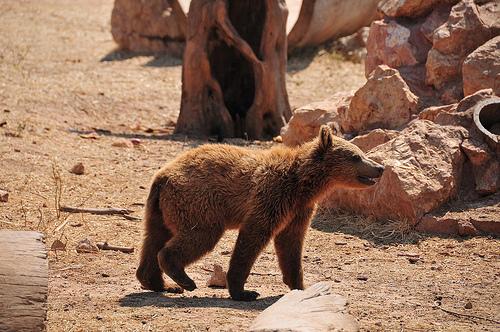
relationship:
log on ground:
[2, 228, 52, 330] [2, 4, 492, 328]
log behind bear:
[0, 228, 52, 331] [125, 117, 399, 294]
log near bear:
[2, 228, 52, 330] [139, 124, 392, 304]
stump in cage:
[168, 0, 294, 146] [2, 0, 497, 331]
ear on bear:
[324, 117, 340, 138] [139, 124, 392, 304]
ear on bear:
[317, 124, 333, 148] [139, 124, 392, 304]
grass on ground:
[303, 220, 496, 329] [2, 4, 492, 328]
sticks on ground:
[303, 208, 497, 327] [2, 4, 492, 328]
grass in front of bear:
[303, 220, 496, 329] [139, 124, 392, 304]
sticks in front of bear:
[303, 208, 497, 327] [139, 124, 392, 304]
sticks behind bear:
[0, 2, 180, 329] [119, 113, 389, 305]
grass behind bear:
[0, 0, 187, 328] [119, 113, 389, 305]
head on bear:
[314, 120, 387, 188] [119, 113, 389, 305]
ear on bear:
[317, 120, 333, 150] [132, 117, 382, 302]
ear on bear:
[324, 120, 340, 138] [132, 117, 382, 302]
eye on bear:
[347, 155, 361, 162] [139, 124, 392, 304]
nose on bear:
[371, 160, 388, 174] [125, 117, 399, 294]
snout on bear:
[371, 160, 388, 177] [139, 124, 392, 304]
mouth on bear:
[353, 169, 383, 188] [139, 124, 392, 304]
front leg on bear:
[226, 210, 284, 307] [139, 124, 392, 304]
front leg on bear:
[271, 220, 306, 289] [139, 124, 392, 304]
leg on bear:
[157, 209, 224, 279] [139, 124, 392, 304]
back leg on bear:
[137, 202, 184, 296] [139, 124, 392, 304]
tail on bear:
[140, 163, 181, 213] [139, 124, 392, 304]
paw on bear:
[219, 286, 264, 303] [139, 124, 392, 304]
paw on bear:
[171, 272, 200, 291] [139, 124, 392, 304]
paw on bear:
[138, 254, 168, 289] [139, 124, 392, 304]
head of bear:
[318, 120, 386, 190] [141, 164, 349, 332]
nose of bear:
[376, 165, 385, 174] [128, 123, 394, 321]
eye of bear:
[347, 155, 361, 162] [132, 135, 388, 272]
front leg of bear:
[273, 211, 313, 289] [120, 125, 369, 332]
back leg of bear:
[137, 197, 174, 287] [138, 165, 331, 328]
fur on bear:
[191, 152, 257, 196] [139, 124, 392, 304]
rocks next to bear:
[382, 99, 455, 204] [142, 142, 378, 321]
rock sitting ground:
[294, 57, 398, 127] [371, 250, 468, 290]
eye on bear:
[345, 152, 360, 164] [135, 121, 387, 301]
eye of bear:
[347, 155, 361, 162] [131, 112, 402, 308]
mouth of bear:
[356, 175, 383, 187] [139, 124, 392, 304]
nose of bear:
[376, 165, 385, 174] [139, 124, 392, 304]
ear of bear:
[317, 124, 333, 148] [119, 113, 389, 305]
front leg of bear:
[226, 211, 291, 290] [139, 124, 392, 304]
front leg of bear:
[226, 211, 291, 290] [135, 121, 387, 301]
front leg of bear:
[273, 211, 313, 289] [135, 121, 387, 301]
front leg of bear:
[226, 211, 291, 290] [131, 112, 402, 308]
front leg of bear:
[273, 211, 313, 289] [131, 112, 402, 308]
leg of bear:
[157, 209, 224, 279] [131, 112, 402, 308]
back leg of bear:
[137, 197, 174, 287] [131, 112, 402, 308]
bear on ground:
[135, 121, 387, 301] [2, 4, 492, 328]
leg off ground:
[154, 179, 225, 297] [2, 4, 492, 328]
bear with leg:
[135, 121, 387, 301] [154, 179, 225, 297]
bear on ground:
[139, 124, 392, 304] [2, 4, 492, 328]